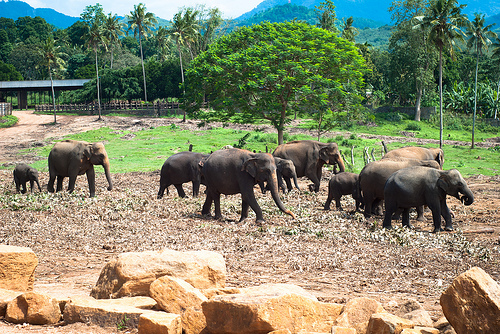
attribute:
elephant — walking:
[382, 160, 474, 239]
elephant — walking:
[382, 140, 443, 160]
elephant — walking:
[358, 151, 392, 221]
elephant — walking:
[327, 167, 363, 217]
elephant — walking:
[272, 134, 342, 194]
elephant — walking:
[276, 153, 297, 195]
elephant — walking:
[200, 143, 290, 227]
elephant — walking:
[158, 146, 209, 209]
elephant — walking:
[42, 137, 115, 203]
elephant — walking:
[6, 160, 42, 201]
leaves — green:
[179, 21, 366, 127]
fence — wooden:
[29, 101, 157, 112]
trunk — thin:
[439, 61, 443, 148]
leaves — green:
[67, 2, 221, 54]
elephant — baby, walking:
[15, 162, 42, 193]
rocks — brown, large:
[0, 240, 496, 332]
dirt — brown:
[0, 102, 97, 147]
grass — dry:
[3, 192, 497, 302]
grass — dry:
[0, 175, 497, 295]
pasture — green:
[37, 122, 497, 180]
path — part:
[0, 96, 84, 147]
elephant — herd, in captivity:
[0, 123, 478, 238]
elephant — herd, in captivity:
[0, 133, 486, 242]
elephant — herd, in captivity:
[6, 133, 476, 234]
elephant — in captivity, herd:
[6, 133, 481, 252]